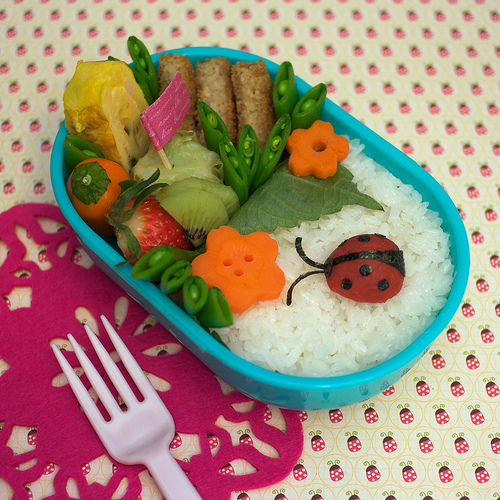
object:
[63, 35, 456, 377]
food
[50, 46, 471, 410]
container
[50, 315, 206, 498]
fork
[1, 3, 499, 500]
table